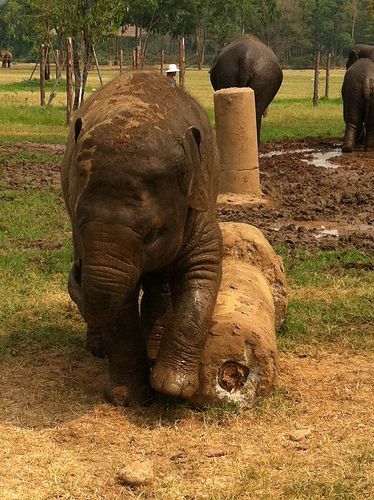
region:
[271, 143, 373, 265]
a mud pit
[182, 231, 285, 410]
an overturned stone pillar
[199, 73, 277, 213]
a stone pillar in the mud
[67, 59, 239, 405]
a young elephant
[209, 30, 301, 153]
an adult elephant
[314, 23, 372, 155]
an adult elephant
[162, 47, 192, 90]
a man wearing a white hat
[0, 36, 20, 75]
an adult elephant in the distance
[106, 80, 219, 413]
mud on the young elephant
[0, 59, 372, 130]
a grassy landscape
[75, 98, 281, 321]
Large brown elephant.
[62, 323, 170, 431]
Elephant is standing in grassy area.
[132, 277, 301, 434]
Elephant is standing near large brown object.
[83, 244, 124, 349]
Elephant has wrinkly skin on leg.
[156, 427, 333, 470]
Grass is brown in front area.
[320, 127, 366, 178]
Elephant is standing in muddy area.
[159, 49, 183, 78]
Person is wearing white hat.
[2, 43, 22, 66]
Large elephant in background.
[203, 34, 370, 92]
2 elephants near person in background.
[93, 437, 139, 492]
Rocks in grassy area near elephant.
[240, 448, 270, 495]
the ground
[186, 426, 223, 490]
the ground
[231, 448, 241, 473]
the ground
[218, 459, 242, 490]
the ground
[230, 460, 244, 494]
the ground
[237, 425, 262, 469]
the ground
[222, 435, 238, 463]
the ground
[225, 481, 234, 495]
the ground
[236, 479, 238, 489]
the ground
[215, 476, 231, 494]
the ground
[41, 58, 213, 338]
animal in the grass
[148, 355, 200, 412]
foot of the animal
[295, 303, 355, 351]
grass on the ground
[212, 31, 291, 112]
elephant not facing the camera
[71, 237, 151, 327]
trunk of the elephant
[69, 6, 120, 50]
tree next to the elephant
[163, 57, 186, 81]
person wearing a hat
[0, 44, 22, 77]
elephant in the background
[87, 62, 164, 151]
dirt on the elephant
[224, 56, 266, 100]
tail of the elephant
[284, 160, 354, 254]
brown mud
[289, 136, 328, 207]
brown mud